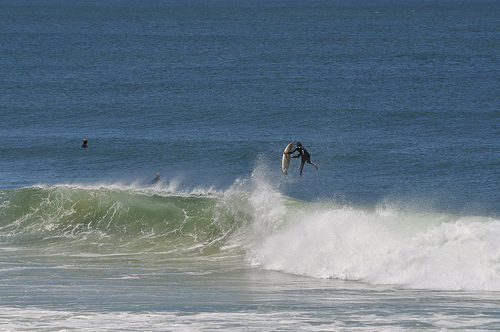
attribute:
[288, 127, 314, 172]
person — holding, carrying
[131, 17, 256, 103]
ocean — flat, water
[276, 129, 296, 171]
surfboard — white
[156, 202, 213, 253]
foam — white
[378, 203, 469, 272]
wave — large, crashing, cresting, cap, small, tidal, clear, splashing, rough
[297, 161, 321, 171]
legs — straight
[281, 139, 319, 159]
wetsuit — worn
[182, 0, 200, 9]
water — spraying, sea salt, party, blue